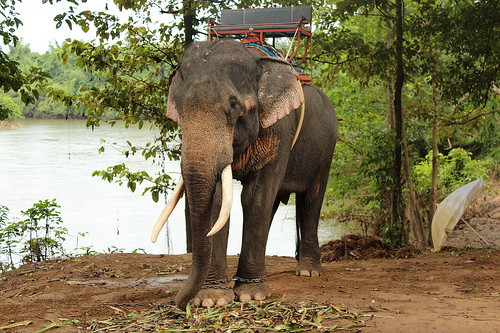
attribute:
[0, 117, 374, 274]
water — still, dirty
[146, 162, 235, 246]
tusks — big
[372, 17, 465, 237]
tree — small, tall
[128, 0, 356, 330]
elephant — grey, big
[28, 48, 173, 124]
trees — thick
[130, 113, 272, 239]
elephant nostril — brown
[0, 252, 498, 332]
floor — rugged, muddy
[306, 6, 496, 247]
plants — rare, green, yellow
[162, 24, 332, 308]
elephant — standing still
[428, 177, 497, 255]
umbrella — white, yellow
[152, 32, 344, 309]
elephant — big, grey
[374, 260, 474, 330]
ground — brown, sandy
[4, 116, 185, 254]
river — dirty, surrounded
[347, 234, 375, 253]
dirt — grassy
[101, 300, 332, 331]
pile — small